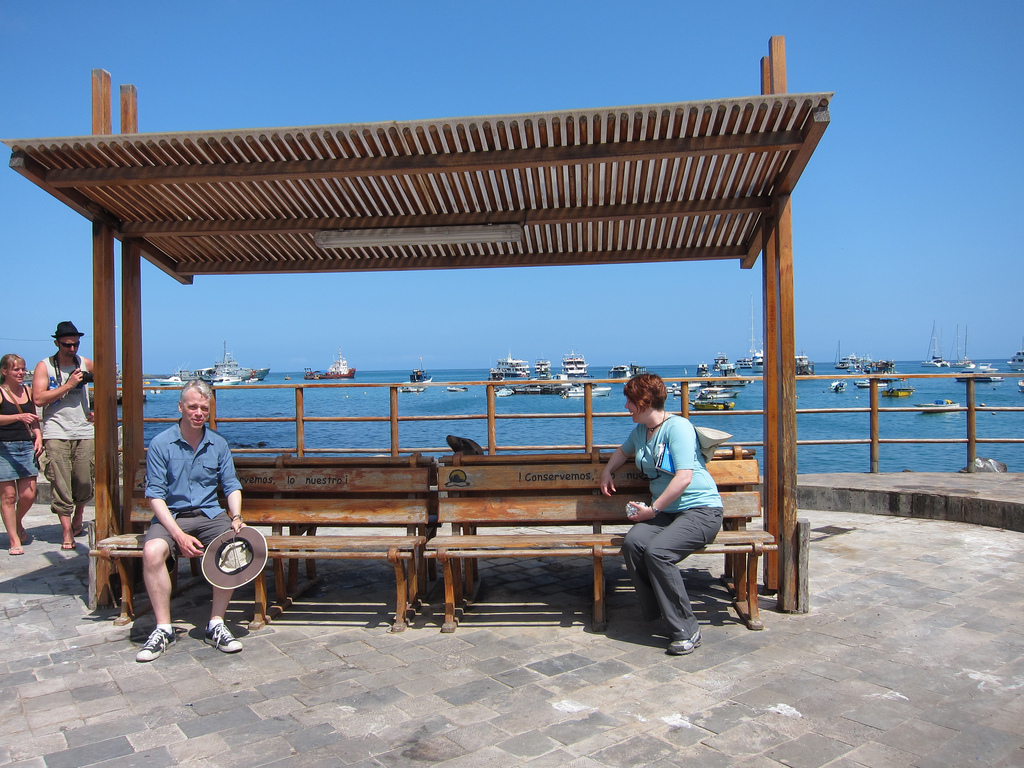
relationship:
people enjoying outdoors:
[0, 288, 804, 656] [11, 19, 990, 717]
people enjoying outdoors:
[0, 321, 725, 662] [11, 19, 990, 717]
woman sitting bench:
[600, 372, 724, 656] [111, 426, 794, 638]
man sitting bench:
[135, 378, 247, 663] [113, 439, 785, 614]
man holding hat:
[135, 378, 247, 663] [202, 510, 289, 617]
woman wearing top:
[588, 372, 716, 681] [614, 417, 723, 517]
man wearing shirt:
[137, 378, 265, 657] [148, 426, 244, 528]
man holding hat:
[135, 378, 247, 663] [195, 519, 271, 587]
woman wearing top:
[0, 354, 42, 588] [3, 395, 34, 443]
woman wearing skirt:
[0, 354, 43, 556] [5, 443, 57, 483]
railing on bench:
[139, 378, 762, 476] [113, 439, 785, 614]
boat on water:
[914, 395, 961, 414] [119, 359, 992, 470]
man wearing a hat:
[32, 315, 100, 551] [47, 318, 86, 344]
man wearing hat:
[32, 315, 100, 551] [39, 318, 89, 355]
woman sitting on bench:
[600, 372, 724, 656] [411, 443, 787, 629]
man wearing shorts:
[137, 378, 265, 657] [150, 512, 233, 547]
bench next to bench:
[89, 448, 437, 637] [411, 443, 787, 629]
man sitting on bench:
[137, 378, 265, 657] [87, 446, 438, 615]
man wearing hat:
[31, 316, 99, 552] [53, 322, 82, 344]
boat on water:
[188, 333, 984, 433] [826, 410, 939, 447]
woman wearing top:
[0, 354, 43, 556] [7, 389, 36, 450]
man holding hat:
[135, 378, 247, 663] [197, 521, 278, 595]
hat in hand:
[197, 521, 278, 595] [178, 521, 269, 586]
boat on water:
[916, 379, 977, 431] [520, 359, 1013, 509]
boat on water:
[849, 359, 923, 414] [650, 342, 1000, 468]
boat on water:
[829, 348, 916, 401] [777, 357, 1007, 496]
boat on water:
[684, 365, 737, 409] [687, 363, 1022, 498]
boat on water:
[689, 342, 767, 414] [322, 318, 647, 418]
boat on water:
[505, 353, 592, 406] [436, 379, 633, 479]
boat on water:
[393, 348, 435, 407] [237, 365, 588, 502]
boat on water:
[300, 353, 370, 392] [199, 351, 638, 512]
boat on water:
[175, 353, 294, 406] [177, 357, 588, 476]